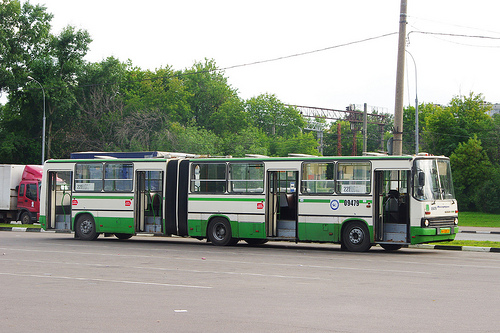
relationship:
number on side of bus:
[342, 199, 360, 207] [38, 154, 460, 253]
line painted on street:
[0, 271, 211, 289] [3, 228, 500, 331]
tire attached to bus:
[74, 214, 98, 237] [38, 154, 460, 253]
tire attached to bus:
[205, 215, 237, 246] [38, 154, 460, 253]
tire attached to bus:
[340, 220, 371, 253] [38, 154, 460, 253]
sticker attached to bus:
[71, 199, 78, 206] [38, 154, 460, 253]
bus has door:
[38, 154, 460, 253] [375, 168, 410, 237]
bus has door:
[38, 154, 460, 253] [265, 171, 297, 239]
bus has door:
[38, 154, 460, 253] [135, 171, 164, 238]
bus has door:
[38, 154, 460, 253] [48, 171, 74, 230]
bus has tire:
[38, 154, 460, 253] [74, 214, 98, 237]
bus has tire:
[38, 154, 460, 253] [205, 215, 237, 246]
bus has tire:
[38, 154, 460, 253] [340, 220, 371, 253]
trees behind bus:
[0, 2, 322, 162] [38, 154, 460, 253]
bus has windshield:
[38, 154, 460, 253] [410, 157, 454, 201]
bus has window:
[38, 154, 460, 253] [73, 162, 105, 191]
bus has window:
[38, 154, 460, 253] [103, 162, 133, 187]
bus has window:
[38, 154, 460, 253] [188, 161, 227, 192]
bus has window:
[38, 154, 460, 253] [228, 162, 264, 191]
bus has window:
[38, 154, 460, 253] [300, 161, 335, 194]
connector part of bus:
[161, 160, 189, 236] [38, 154, 460, 253]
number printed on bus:
[342, 199, 360, 207] [38, 154, 460, 253]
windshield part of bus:
[410, 157, 454, 201] [38, 154, 460, 253]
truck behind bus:
[0, 165, 43, 226] [38, 154, 460, 253]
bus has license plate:
[38, 154, 460, 253] [438, 228, 451, 236]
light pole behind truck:
[25, 75, 48, 163] [0, 165, 43, 226]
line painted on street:
[2, 247, 417, 276] [3, 228, 500, 331]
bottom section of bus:
[95, 217, 372, 243] [38, 154, 460, 253]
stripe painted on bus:
[71, 195, 372, 204] [38, 154, 460, 253]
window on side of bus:
[336, 159, 369, 194] [38, 154, 460, 253]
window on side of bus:
[300, 161, 335, 194] [38, 154, 460, 253]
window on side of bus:
[228, 162, 264, 191] [38, 154, 460, 253]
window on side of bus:
[188, 161, 227, 192] [38, 154, 460, 253]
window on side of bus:
[103, 162, 133, 187] [38, 154, 460, 253]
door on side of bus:
[135, 171, 164, 238] [38, 154, 460, 253]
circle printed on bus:
[328, 199, 339, 210] [38, 154, 460, 253]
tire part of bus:
[340, 220, 371, 253] [38, 154, 460, 253]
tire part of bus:
[205, 215, 237, 246] [38, 154, 460, 253]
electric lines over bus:
[0, 30, 400, 98] [38, 154, 460, 253]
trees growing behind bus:
[0, 2, 322, 162] [38, 154, 460, 253]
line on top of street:
[0, 271, 211, 289] [3, 228, 500, 331]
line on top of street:
[2, 247, 417, 276] [3, 228, 500, 331]